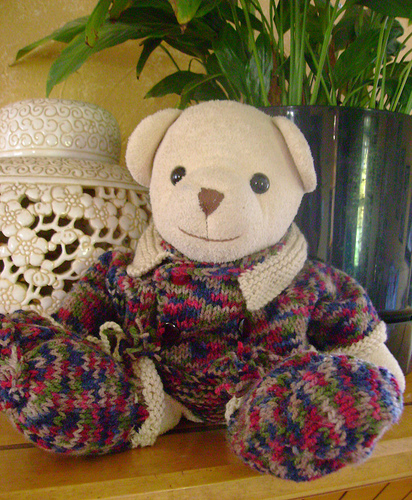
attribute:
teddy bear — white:
[154, 103, 387, 437]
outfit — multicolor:
[49, 239, 400, 457]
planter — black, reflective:
[242, 49, 406, 316]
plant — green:
[21, 1, 401, 103]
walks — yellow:
[84, 58, 167, 98]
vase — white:
[2, 99, 115, 312]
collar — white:
[147, 222, 307, 315]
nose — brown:
[195, 177, 230, 217]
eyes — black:
[166, 163, 283, 202]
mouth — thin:
[183, 203, 233, 254]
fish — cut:
[132, 456, 216, 497]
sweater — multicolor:
[20, 235, 411, 466]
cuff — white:
[323, 316, 391, 367]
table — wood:
[59, 458, 245, 495]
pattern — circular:
[16, 110, 124, 169]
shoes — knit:
[41, 324, 378, 479]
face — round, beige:
[131, 69, 315, 268]